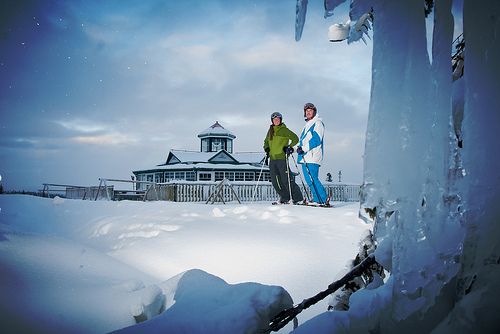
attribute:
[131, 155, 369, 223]
fence — long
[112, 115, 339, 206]
house — large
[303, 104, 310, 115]
hair — long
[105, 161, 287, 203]
wooden fence — long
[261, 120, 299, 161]
coat — green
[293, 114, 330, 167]
coat — green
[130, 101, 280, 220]
house — large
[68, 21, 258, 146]
sky — cloudy